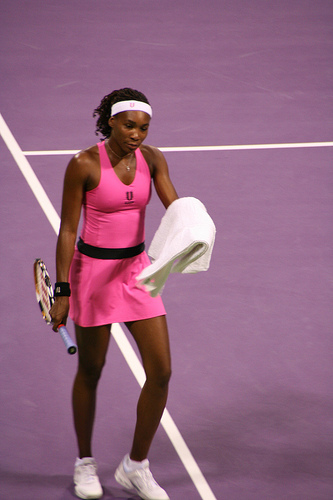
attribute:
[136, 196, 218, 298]
towel — white, folded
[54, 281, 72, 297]
wrist band — black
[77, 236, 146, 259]
belt — black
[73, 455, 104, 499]
sneaker — white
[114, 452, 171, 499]
sneaker — white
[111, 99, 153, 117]
head band — white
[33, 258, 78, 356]
tennis racquet — multi colored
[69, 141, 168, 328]
dress — pink, sleeveless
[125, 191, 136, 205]
logo — black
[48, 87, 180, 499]
girl — walking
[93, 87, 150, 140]
hair — styled